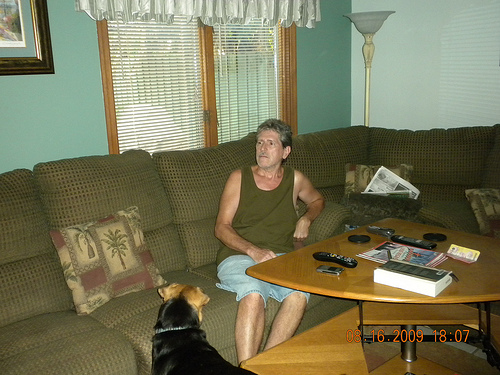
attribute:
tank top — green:
[224, 161, 297, 258]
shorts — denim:
[217, 253, 298, 300]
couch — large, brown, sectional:
[3, 107, 495, 360]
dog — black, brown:
[135, 283, 277, 368]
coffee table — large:
[241, 217, 498, 372]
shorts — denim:
[222, 255, 302, 294]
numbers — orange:
[344, 324, 476, 347]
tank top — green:
[217, 162, 297, 254]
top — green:
[214, 163, 299, 266]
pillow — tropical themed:
[52, 202, 167, 321]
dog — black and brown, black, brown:
[146, 275, 256, 373]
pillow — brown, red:
[35, 199, 190, 322]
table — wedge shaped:
[248, 213, 498, 321]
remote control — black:
[313, 250, 356, 268]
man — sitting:
[217, 116, 314, 340]